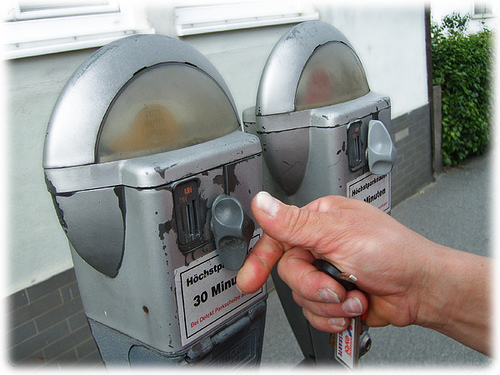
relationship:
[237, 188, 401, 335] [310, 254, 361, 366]
hand holding keys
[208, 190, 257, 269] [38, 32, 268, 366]
knob on parking meter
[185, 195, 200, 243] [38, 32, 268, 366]
coin slot on parking meter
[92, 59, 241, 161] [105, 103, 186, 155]
meter window with flag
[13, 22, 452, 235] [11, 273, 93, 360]
building with foundation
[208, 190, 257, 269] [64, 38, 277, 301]
knob of parking meter